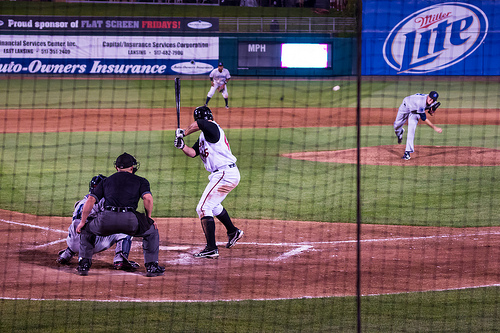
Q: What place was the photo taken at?
A: It was taken at the field.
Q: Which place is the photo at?
A: It is at the field.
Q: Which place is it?
A: It is a field.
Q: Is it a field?
A: Yes, it is a field.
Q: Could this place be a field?
A: Yes, it is a field.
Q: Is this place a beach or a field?
A: It is a field.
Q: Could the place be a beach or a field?
A: It is a field.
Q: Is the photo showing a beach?
A: No, the picture is showing a field.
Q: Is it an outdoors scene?
A: Yes, it is outdoors.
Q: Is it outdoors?
A: Yes, it is outdoors.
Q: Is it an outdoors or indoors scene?
A: It is outdoors.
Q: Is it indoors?
A: No, it is outdoors.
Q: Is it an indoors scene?
A: No, it is outdoors.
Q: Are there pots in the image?
A: No, there are no pots.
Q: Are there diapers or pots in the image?
A: No, there are no pots or diapers.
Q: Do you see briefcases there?
A: No, there are no briefcases.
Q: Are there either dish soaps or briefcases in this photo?
A: No, there are no briefcases or dish soaps.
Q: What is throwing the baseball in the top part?
A: The pitcher is throwing the baseball.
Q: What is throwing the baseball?
A: The pitcher is throwing the baseball.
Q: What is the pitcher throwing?
A: The pitcher is throwing the baseball.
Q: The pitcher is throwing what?
A: The pitcher is throwing the baseball.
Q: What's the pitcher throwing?
A: The pitcher is throwing the baseball.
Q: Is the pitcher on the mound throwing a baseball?
A: Yes, the pitcher is throwing a baseball.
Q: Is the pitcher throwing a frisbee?
A: No, the pitcher is throwing a baseball.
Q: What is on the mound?
A: The pitcher is on the mound.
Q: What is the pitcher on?
A: The pitcher is on the mound.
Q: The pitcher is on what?
A: The pitcher is on the mound.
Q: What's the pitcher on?
A: The pitcher is on the mound.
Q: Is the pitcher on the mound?
A: Yes, the pitcher is on the mound.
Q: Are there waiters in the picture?
A: No, there are no waiters.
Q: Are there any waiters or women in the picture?
A: No, there are no waiters or women.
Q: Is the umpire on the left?
A: Yes, the umpire is on the left of the image.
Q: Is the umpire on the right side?
A: No, the umpire is on the left of the image.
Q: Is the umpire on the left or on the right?
A: The umpire is on the left of the image.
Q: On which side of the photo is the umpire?
A: The umpire is on the left of the image.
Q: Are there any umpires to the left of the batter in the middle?
A: Yes, there is an umpire to the left of the batter.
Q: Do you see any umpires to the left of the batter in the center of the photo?
A: Yes, there is an umpire to the left of the batter.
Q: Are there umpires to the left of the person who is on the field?
A: Yes, there is an umpire to the left of the batter.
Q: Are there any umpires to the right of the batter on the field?
A: No, the umpire is to the left of the batter.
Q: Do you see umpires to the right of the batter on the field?
A: No, the umpire is to the left of the batter.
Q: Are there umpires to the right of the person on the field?
A: No, the umpire is to the left of the batter.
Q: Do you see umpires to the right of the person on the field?
A: No, the umpire is to the left of the batter.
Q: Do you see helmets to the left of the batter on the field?
A: No, there is an umpire to the left of the batter.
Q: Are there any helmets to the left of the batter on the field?
A: No, there is an umpire to the left of the batter.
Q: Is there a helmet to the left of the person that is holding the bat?
A: No, there is an umpire to the left of the batter.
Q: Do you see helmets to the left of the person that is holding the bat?
A: No, there is an umpire to the left of the batter.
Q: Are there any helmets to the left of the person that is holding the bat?
A: No, there is an umpire to the left of the batter.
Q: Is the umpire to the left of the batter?
A: Yes, the umpire is to the left of the batter.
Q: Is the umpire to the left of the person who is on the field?
A: Yes, the umpire is to the left of the batter.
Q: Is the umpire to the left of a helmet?
A: No, the umpire is to the left of the batter.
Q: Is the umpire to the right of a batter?
A: No, the umpire is to the left of a batter.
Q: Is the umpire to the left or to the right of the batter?
A: The umpire is to the left of the batter.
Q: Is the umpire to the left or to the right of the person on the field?
A: The umpire is to the left of the batter.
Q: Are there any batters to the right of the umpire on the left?
A: Yes, there is a batter to the right of the umpire.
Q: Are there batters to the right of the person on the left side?
A: Yes, there is a batter to the right of the umpire.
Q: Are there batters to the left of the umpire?
A: No, the batter is to the right of the umpire.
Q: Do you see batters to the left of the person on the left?
A: No, the batter is to the right of the umpire.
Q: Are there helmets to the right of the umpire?
A: No, there is a batter to the right of the umpire.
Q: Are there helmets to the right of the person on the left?
A: No, there is a batter to the right of the umpire.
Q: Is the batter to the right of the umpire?
A: Yes, the batter is to the right of the umpire.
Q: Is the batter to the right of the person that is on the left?
A: Yes, the batter is to the right of the umpire.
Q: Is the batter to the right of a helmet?
A: No, the batter is to the right of the umpire.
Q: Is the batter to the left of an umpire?
A: No, the batter is to the right of an umpire.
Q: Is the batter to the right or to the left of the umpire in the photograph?
A: The batter is to the right of the umpire.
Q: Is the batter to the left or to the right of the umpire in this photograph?
A: The batter is to the right of the umpire.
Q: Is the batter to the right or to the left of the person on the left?
A: The batter is to the right of the umpire.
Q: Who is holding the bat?
A: The batter is holding the bat.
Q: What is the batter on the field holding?
A: The batter is holding the bat.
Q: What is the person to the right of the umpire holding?
A: The batter is holding the bat.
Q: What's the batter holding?
A: The batter is holding the bat.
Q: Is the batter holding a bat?
A: Yes, the batter is holding a bat.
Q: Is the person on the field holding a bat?
A: Yes, the batter is holding a bat.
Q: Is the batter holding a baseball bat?
A: No, the batter is holding a bat.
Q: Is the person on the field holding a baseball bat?
A: No, the batter is holding a bat.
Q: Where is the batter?
A: The batter is on the field.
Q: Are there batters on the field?
A: Yes, there is a batter on the field.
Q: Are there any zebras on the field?
A: No, there is a batter on the field.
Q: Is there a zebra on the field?
A: No, there is a batter on the field.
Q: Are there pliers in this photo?
A: No, there are no pliers.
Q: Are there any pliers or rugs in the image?
A: No, there are no pliers or rugs.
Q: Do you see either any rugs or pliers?
A: No, there are no pliers or rugs.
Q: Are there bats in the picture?
A: Yes, there is a bat.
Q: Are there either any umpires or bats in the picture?
A: Yes, there is a bat.